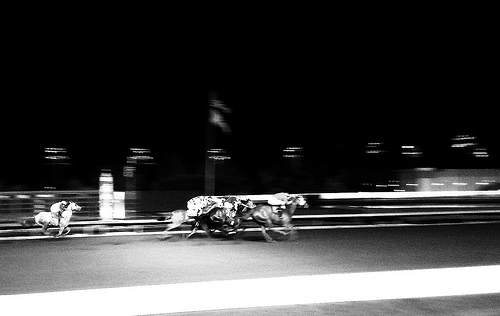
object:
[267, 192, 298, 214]
rider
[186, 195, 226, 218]
rider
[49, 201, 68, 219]
rider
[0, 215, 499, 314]
track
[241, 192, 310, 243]
horse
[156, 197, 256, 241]
horse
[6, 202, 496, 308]
track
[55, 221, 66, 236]
legs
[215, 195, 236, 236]
man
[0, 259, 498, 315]
fence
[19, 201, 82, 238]
horse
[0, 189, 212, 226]
fence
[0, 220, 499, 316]
race track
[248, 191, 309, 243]
jockey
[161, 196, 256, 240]
jockey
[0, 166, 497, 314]
race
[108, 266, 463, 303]
rail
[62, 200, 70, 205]
hat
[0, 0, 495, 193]
sky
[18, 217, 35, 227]
tail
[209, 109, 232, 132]
flag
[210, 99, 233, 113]
flag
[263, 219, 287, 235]
legs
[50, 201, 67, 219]
man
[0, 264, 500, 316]
light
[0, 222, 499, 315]
ground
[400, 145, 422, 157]
lights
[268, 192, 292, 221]
man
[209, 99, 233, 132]
flags flying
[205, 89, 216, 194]
pole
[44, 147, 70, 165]
lights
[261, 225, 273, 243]
legs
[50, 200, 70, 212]
jokcey